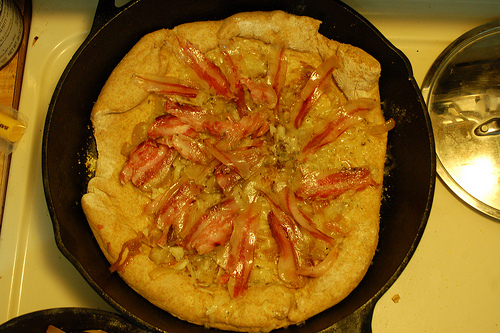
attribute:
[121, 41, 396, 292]
onions — brown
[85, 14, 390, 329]
crust — brown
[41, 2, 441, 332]
skillet — brown, black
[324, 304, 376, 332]
handle — black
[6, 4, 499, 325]
stove — white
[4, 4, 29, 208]
cabinet — wooden, brown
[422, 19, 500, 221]
lid — silver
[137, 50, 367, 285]
cheese — white